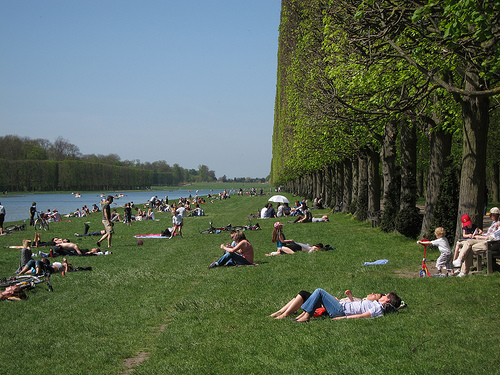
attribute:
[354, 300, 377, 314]
shirt — part 